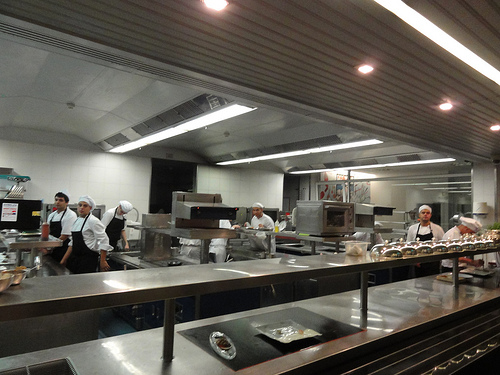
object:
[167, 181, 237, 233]
warmer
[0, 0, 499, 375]
kitchen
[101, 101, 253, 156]
lights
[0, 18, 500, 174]
ceiling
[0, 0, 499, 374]
cafeteria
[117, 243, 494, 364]
shelf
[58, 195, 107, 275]
cooker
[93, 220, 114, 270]
left arm